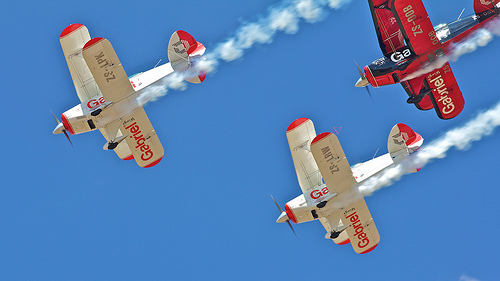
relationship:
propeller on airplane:
[257, 192, 318, 244] [49, 23, 208, 169]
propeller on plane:
[350, 60, 375, 101] [358, 1, 498, 123]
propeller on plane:
[271, 196, 300, 233] [274, 119, 425, 253]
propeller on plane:
[44, 108, 75, 149] [51, 19, 208, 164]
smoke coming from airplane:
[231, 18, 287, 46] [51, 23, 209, 172]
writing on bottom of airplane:
[122, 120, 154, 164] [44, 7, 221, 180]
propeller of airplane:
[270, 200, 297, 237] [354, 2, 499, 117]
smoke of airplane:
[133, 2, 345, 107] [49, 23, 208, 169]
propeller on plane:
[44, 108, 75, 149] [29, 12, 229, 179]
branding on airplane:
[32, 18, 242, 228] [41, 20, 215, 172]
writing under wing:
[118, 119, 164, 179] [83, 120, 174, 163]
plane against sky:
[358, 1, 498, 123] [0, 0, 499, 280]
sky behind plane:
[0, 0, 499, 280] [47, 20, 214, 171]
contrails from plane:
[21, 19, 220, 189] [51, 19, 208, 164]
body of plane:
[55, 54, 194, 132] [47, 20, 214, 171]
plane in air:
[270, 84, 450, 267] [9, 7, 496, 279]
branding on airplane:
[120, 106, 170, 176] [240, 97, 440, 279]